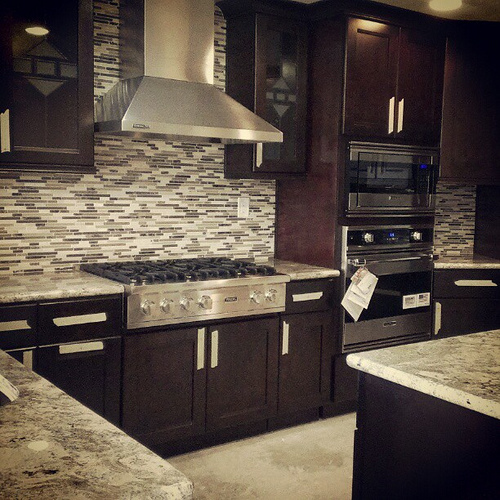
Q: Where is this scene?
A: The kitchen.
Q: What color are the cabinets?
A: Brown.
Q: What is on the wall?
A: Back splash.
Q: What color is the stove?
A: Silver.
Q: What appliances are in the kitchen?
A: Stove and oven.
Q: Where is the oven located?
A: To the left of the stove.